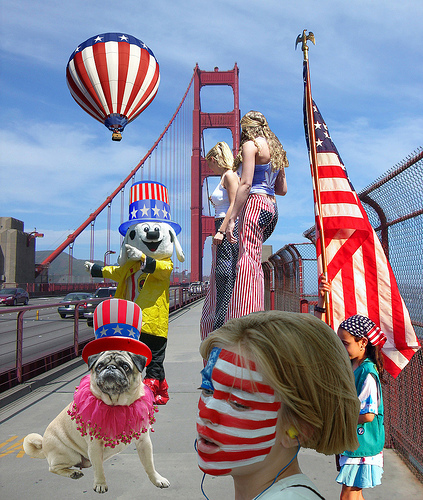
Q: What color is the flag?
A: Red, white and blue.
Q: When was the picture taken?
A: Daytime.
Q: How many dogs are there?
A: One.